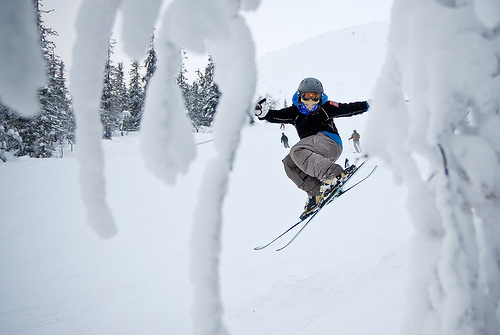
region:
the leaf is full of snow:
[126, 221, 328, 331]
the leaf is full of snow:
[167, 194, 279, 328]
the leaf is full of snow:
[130, 195, 230, 255]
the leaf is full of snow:
[115, 150, 225, 255]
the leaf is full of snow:
[125, 166, 260, 281]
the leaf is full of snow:
[121, 156, 191, 236]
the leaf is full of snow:
[135, 140, 200, 215]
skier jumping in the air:
[266, 69, 377, 258]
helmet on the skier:
[287, 72, 327, 118]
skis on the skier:
[261, 150, 362, 279]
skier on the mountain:
[347, 127, 369, 155]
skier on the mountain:
[279, 127, 289, 149]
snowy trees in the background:
[102, 75, 150, 135]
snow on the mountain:
[17, 245, 122, 317]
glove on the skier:
[249, 95, 271, 130]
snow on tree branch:
[187, 201, 229, 327]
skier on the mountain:
[275, 122, 286, 130]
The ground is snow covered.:
[61, 214, 213, 308]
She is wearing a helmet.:
[270, 52, 323, 133]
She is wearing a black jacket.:
[236, 90, 413, 170]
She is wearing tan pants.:
[246, 76, 350, 216]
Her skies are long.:
[254, 159, 380, 284]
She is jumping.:
[254, 73, 391, 280]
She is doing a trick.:
[234, 67, 404, 229]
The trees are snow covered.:
[25, 91, 100, 183]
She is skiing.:
[9, 32, 444, 314]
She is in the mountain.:
[25, 19, 432, 330]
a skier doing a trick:
[240, 67, 380, 278]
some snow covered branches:
[6, 5, 498, 323]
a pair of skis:
[257, 150, 380, 261]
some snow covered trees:
[0, 25, 236, 165]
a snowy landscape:
[12, 55, 450, 330]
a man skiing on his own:
[346, 123, 373, 163]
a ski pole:
[178, 85, 281, 157]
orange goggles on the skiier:
[291, 86, 331, 103]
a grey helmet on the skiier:
[300, 74, 324, 97]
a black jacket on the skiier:
[266, 95, 363, 145]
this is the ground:
[8, 179, 65, 319]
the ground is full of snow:
[2, 187, 62, 306]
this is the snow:
[15, 175, 60, 321]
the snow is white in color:
[11, 182, 62, 312]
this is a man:
[261, 69, 372, 258]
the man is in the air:
[266, 81, 373, 203]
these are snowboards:
[256, 162, 368, 252]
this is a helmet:
[295, 77, 323, 91]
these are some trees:
[45, 42, 73, 159]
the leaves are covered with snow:
[107, 76, 133, 123]